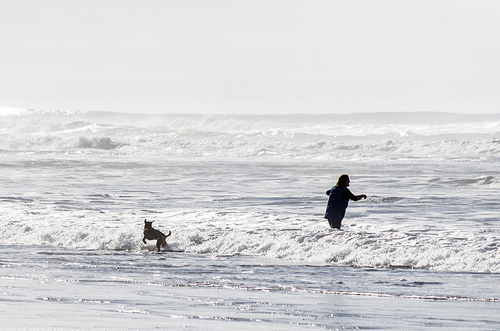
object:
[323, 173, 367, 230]
person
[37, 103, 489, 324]
beach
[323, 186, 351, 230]
cloths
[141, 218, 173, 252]
dog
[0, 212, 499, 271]
waves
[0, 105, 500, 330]
water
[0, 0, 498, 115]
sky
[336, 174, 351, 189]
hair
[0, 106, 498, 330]
ocean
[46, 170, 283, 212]
ripples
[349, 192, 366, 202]
arm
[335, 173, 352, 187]
head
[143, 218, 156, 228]
head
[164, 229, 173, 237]
tail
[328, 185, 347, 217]
torso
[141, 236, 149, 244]
feet